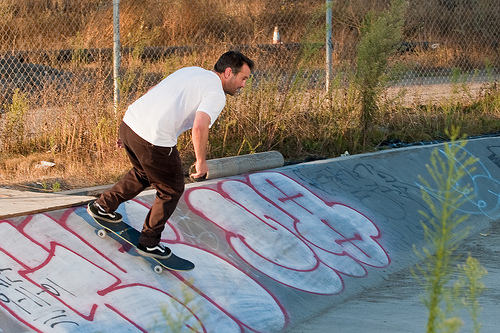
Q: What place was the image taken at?
A: It was taken at the pavement.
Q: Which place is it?
A: It is a pavement.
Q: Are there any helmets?
A: No, there are no helmets.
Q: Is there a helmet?
A: No, there are no helmets.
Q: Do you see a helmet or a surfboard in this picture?
A: No, there are no helmets or surfboards.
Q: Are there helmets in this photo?
A: No, there are no helmets.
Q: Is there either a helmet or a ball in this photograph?
A: No, there are no helmets or balls.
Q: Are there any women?
A: No, there are no women.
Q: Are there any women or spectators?
A: No, there are no women or spectators.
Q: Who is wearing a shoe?
A: The man is wearing a shoe.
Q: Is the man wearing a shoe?
A: Yes, the man is wearing a shoe.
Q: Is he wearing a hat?
A: No, the man is wearing a shoe.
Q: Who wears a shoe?
A: The man wears a shoe.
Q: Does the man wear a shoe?
A: Yes, the man wears a shoe.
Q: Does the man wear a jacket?
A: No, the man wears a shoe.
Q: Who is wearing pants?
A: The man is wearing pants.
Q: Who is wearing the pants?
A: The man is wearing pants.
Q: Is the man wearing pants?
A: Yes, the man is wearing pants.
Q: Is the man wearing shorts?
A: No, the man is wearing pants.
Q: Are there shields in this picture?
A: No, there are no shields.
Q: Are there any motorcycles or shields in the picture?
A: No, there are no shields or motorcycles.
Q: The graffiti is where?
A: The graffiti is on the pavement.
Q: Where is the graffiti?
A: The graffiti is on the pavement.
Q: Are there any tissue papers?
A: No, there are no tissue papers.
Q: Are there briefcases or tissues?
A: No, there are no tissues or briefcases.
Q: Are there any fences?
A: Yes, there is a fence.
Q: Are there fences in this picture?
A: Yes, there is a fence.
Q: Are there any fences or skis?
A: Yes, there is a fence.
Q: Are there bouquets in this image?
A: No, there are no bouquets.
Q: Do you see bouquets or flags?
A: No, there are no bouquets or flags.